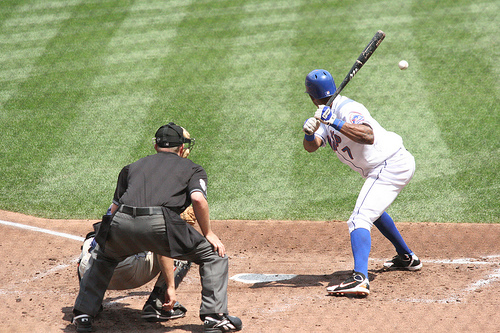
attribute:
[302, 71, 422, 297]
uniform — baseball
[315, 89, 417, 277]
baseball uniform — piece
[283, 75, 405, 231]
uniform — piece, baseball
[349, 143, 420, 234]
uniform — piece, baseball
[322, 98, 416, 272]
uniform — baseball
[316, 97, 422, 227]
baseball uniform — piece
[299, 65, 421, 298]
baseball uniform — piece